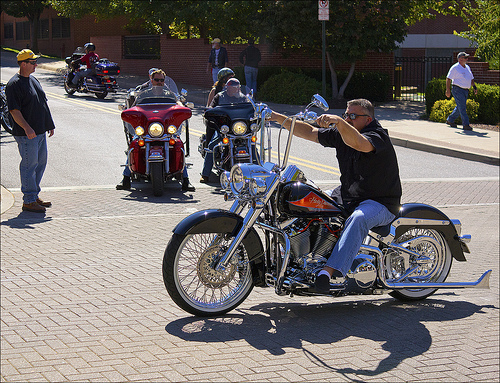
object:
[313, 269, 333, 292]
shoes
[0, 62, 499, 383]
floor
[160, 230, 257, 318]
tires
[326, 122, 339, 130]
handles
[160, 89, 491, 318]
bike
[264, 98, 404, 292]
man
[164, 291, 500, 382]
shade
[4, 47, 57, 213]
man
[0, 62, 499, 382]
road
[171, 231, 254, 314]
rim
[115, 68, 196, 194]
people